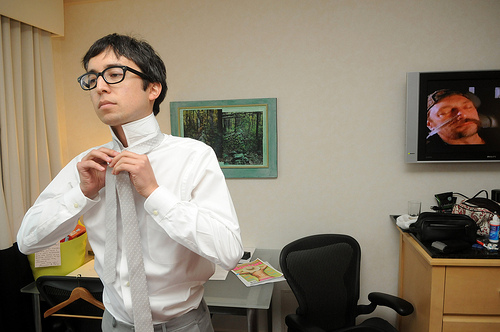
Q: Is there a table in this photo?
A: Yes, there is a table.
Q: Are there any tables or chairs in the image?
A: Yes, there is a table.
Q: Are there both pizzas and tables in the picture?
A: No, there is a table but no pizzas.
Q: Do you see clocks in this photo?
A: No, there are no clocks.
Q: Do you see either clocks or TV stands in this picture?
A: No, there are no clocks or TV stands.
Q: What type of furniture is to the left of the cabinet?
A: The piece of furniture is a table.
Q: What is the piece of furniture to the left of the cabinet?
A: The piece of furniture is a table.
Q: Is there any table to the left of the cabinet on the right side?
A: Yes, there is a table to the left of the cabinet.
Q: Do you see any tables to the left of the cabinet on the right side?
A: Yes, there is a table to the left of the cabinet.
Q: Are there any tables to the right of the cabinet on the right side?
A: No, the table is to the left of the cabinet.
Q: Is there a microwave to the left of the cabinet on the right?
A: No, there is a table to the left of the cabinet.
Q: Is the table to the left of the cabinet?
A: Yes, the table is to the left of the cabinet.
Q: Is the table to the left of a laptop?
A: No, the table is to the left of the cabinet.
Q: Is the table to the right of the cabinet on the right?
A: No, the table is to the left of the cabinet.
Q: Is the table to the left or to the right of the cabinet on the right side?
A: The table is to the left of the cabinet.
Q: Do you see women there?
A: No, there are no women.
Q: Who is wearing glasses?
A: The boy is wearing glasses.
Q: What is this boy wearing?
A: The boy is wearing glasses.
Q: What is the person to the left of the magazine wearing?
A: The boy is wearing glasses.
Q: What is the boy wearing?
A: The boy is wearing glasses.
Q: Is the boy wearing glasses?
A: Yes, the boy is wearing glasses.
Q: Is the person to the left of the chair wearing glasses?
A: Yes, the boy is wearing glasses.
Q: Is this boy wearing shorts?
A: No, the boy is wearing glasses.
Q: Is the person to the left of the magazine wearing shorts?
A: No, the boy is wearing glasses.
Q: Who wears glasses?
A: The boy wears glasses.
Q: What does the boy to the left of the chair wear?
A: The boy wears glasses.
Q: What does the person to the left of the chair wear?
A: The boy wears glasses.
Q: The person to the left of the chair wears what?
A: The boy wears glasses.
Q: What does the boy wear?
A: The boy wears glasses.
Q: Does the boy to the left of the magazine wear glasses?
A: Yes, the boy wears glasses.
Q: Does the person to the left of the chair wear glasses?
A: Yes, the boy wears glasses.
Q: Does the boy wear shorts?
A: No, the boy wears glasses.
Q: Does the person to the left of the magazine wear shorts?
A: No, the boy wears glasses.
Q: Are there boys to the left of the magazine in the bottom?
A: Yes, there is a boy to the left of the magazine.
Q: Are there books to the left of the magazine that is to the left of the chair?
A: No, there is a boy to the left of the magazine.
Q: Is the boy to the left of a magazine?
A: Yes, the boy is to the left of a magazine.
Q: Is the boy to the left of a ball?
A: No, the boy is to the left of a magazine.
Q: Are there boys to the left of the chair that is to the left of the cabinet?
A: Yes, there is a boy to the left of the chair.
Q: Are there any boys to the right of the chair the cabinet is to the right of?
A: No, the boy is to the left of the chair.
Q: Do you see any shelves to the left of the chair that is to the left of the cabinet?
A: No, there is a boy to the left of the chair.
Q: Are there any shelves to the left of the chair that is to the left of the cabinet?
A: No, there is a boy to the left of the chair.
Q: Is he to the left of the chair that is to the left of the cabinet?
A: Yes, the boy is to the left of the chair.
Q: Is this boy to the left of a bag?
A: No, the boy is to the left of the chair.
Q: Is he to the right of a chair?
A: No, the boy is to the left of a chair.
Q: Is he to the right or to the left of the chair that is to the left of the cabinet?
A: The boy is to the left of the chair.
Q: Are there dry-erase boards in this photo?
A: No, there are no dry-erase boards.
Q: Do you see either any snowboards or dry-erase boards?
A: No, there are no dry-erase boards or snowboards.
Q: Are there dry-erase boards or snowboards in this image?
A: No, there are no dry-erase boards or snowboards.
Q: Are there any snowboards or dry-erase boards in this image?
A: No, there are no dry-erase boards or snowboards.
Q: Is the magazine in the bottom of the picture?
A: Yes, the magazine is in the bottom of the image.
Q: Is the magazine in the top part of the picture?
A: No, the magazine is in the bottom of the image.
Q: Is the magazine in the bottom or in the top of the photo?
A: The magazine is in the bottom of the image.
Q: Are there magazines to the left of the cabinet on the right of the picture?
A: Yes, there is a magazine to the left of the cabinet.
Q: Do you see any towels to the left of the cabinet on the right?
A: No, there is a magazine to the left of the cabinet.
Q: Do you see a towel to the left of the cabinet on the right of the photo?
A: No, there is a magazine to the left of the cabinet.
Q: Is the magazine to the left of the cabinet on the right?
A: Yes, the magazine is to the left of the cabinet.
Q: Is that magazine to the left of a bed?
A: No, the magazine is to the left of the cabinet.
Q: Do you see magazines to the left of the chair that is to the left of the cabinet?
A: Yes, there is a magazine to the left of the chair.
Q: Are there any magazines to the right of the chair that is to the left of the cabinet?
A: No, the magazine is to the left of the chair.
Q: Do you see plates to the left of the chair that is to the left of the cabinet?
A: No, there is a magazine to the left of the chair.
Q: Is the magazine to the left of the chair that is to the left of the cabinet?
A: Yes, the magazine is to the left of the chair.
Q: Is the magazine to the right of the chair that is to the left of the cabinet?
A: No, the magazine is to the left of the chair.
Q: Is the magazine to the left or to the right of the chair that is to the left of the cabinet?
A: The magazine is to the left of the chair.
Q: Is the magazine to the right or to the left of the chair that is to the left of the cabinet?
A: The magazine is to the left of the chair.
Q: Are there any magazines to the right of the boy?
A: Yes, there is a magazine to the right of the boy.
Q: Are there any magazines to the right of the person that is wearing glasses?
A: Yes, there is a magazine to the right of the boy.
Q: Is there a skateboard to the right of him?
A: No, there is a magazine to the right of the boy.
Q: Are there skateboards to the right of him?
A: No, there is a magazine to the right of the boy.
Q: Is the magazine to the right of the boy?
A: Yes, the magazine is to the right of the boy.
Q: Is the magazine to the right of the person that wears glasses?
A: Yes, the magazine is to the right of the boy.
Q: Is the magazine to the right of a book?
A: No, the magazine is to the right of the boy.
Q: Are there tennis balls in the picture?
A: No, there are no tennis balls.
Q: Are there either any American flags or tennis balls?
A: No, there are no tennis balls or American flags.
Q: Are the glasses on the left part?
A: Yes, the glasses are on the left of the image.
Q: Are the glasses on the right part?
A: No, the glasses are on the left of the image.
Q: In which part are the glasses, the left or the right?
A: The glasses are on the left of the image.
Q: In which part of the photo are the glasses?
A: The glasses are on the left of the image.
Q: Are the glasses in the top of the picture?
A: Yes, the glasses are in the top of the image.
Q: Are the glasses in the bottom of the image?
A: No, the glasses are in the top of the image.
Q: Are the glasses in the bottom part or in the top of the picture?
A: The glasses are in the top of the image.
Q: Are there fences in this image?
A: No, there are no fences.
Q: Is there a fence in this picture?
A: No, there are no fences.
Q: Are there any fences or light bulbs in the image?
A: No, there are no fences or light bulbs.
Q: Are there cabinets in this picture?
A: Yes, there is a cabinet.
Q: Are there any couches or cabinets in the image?
A: Yes, there is a cabinet.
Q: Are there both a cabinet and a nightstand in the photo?
A: No, there is a cabinet but no nightstands.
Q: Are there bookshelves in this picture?
A: No, there are no bookshelves.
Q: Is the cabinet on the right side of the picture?
A: Yes, the cabinet is on the right of the image.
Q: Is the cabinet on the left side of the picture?
A: No, the cabinet is on the right of the image.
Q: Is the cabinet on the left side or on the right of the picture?
A: The cabinet is on the right of the image.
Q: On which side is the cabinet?
A: The cabinet is on the right of the image.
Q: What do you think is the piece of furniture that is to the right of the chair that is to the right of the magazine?
A: The piece of furniture is a cabinet.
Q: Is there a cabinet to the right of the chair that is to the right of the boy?
A: Yes, there is a cabinet to the right of the chair.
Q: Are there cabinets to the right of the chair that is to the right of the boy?
A: Yes, there is a cabinet to the right of the chair.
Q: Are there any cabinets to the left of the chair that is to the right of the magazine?
A: No, the cabinet is to the right of the chair.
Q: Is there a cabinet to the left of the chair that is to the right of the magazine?
A: No, the cabinet is to the right of the chair.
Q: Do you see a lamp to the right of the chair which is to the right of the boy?
A: No, there is a cabinet to the right of the chair.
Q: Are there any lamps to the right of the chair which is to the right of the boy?
A: No, there is a cabinet to the right of the chair.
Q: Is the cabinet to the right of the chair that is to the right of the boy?
A: Yes, the cabinet is to the right of the chair.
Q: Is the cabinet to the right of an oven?
A: No, the cabinet is to the right of the chair.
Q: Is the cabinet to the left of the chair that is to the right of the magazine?
A: No, the cabinet is to the right of the chair.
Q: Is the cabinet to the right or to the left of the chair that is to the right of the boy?
A: The cabinet is to the right of the chair.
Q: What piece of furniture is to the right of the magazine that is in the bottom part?
A: The piece of furniture is a cabinet.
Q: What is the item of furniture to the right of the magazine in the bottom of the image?
A: The piece of furniture is a cabinet.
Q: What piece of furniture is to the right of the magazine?
A: The piece of furniture is a cabinet.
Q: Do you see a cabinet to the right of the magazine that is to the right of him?
A: Yes, there is a cabinet to the right of the magazine.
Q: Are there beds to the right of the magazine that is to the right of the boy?
A: No, there is a cabinet to the right of the magazine.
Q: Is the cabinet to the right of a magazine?
A: Yes, the cabinet is to the right of a magazine.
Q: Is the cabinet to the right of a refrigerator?
A: No, the cabinet is to the right of a magazine.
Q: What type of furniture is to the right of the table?
A: The piece of furniture is a cabinet.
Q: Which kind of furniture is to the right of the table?
A: The piece of furniture is a cabinet.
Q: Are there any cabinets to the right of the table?
A: Yes, there is a cabinet to the right of the table.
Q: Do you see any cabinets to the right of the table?
A: Yes, there is a cabinet to the right of the table.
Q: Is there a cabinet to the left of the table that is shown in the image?
A: No, the cabinet is to the right of the table.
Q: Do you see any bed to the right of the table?
A: No, there is a cabinet to the right of the table.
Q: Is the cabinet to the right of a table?
A: Yes, the cabinet is to the right of a table.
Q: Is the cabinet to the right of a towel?
A: No, the cabinet is to the right of a table.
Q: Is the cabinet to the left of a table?
A: No, the cabinet is to the right of a table.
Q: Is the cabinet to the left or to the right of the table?
A: The cabinet is to the right of the table.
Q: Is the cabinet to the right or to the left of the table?
A: The cabinet is to the right of the table.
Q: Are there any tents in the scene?
A: No, there are no tents.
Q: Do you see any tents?
A: No, there are no tents.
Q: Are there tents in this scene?
A: No, there are no tents.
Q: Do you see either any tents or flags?
A: No, there are no tents or flags.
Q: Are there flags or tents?
A: No, there are no tents or flags.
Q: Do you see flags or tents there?
A: No, there are no tents or flags.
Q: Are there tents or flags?
A: No, there are no tents or flags.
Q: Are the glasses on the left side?
A: Yes, the glasses are on the left of the image.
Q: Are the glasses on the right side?
A: No, the glasses are on the left of the image.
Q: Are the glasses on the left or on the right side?
A: The glasses are on the left of the image.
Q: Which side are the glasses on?
A: The glasses are on the left of the image.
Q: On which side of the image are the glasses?
A: The glasses are on the left of the image.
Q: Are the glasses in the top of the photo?
A: Yes, the glasses are in the top of the image.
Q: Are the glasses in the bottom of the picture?
A: No, the glasses are in the top of the image.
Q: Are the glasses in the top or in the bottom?
A: The glasses are in the top of the image.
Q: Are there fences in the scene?
A: No, there are no fences.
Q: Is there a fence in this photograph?
A: No, there are no fences.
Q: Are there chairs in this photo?
A: Yes, there is a chair.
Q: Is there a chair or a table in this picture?
A: Yes, there is a chair.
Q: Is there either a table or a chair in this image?
A: Yes, there is a chair.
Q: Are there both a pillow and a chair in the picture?
A: No, there is a chair but no pillows.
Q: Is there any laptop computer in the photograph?
A: No, there are no laptops.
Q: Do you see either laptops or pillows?
A: No, there are no laptops or pillows.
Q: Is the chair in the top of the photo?
A: No, the chair is in the bottom of the image.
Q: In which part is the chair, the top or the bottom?
A: The chair is in the bottom of the image.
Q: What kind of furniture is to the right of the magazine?
A: The piece of furniture is a chair.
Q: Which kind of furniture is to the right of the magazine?
A: The piece of furniture is a chair.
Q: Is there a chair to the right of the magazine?
A: Yes, there is a chair to the right of the magazine.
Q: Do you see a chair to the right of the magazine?
A: Yes, there is a chair to the right of the magazine.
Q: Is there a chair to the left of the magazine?
A: No, the chair is to the right of the magazine.